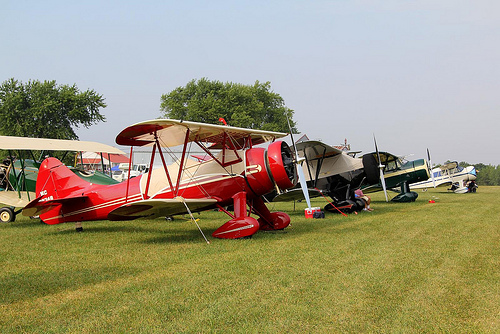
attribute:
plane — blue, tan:
[332, 145, 434, 215]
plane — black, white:
[292, 128, 390, 218]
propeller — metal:
[269, 134, 341, 208]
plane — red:
[26, 114, 298, 245]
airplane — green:
[347, 149, 428, 216]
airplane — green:
[352, 150, 432, 204]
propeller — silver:
[270, 137, 345, 214]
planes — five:
[50, 90, 478, 267]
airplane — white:
[430, 155, 481, 193]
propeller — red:
[244, 137, 301, 207]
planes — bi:
[13, 108, 315, 262]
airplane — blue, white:
[41, 115, 333, 253]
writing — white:
[35, 188, 52, 202]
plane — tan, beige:
[267, 102, 392, 225]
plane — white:
[291, 134, 381, 188]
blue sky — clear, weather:
[265, 30, 350, 78]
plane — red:
[0, 111, 320, 242]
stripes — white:
[75, 174, 236, 210]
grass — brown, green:
[5, 185, 488, 332]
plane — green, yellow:
[348, 134, 435, 211]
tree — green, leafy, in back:
[169, 77, 324, 149]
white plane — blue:
[412, 158, 481, 195]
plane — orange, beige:
[23, 113, 318, 237]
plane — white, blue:
[384, 160, 482, 196]